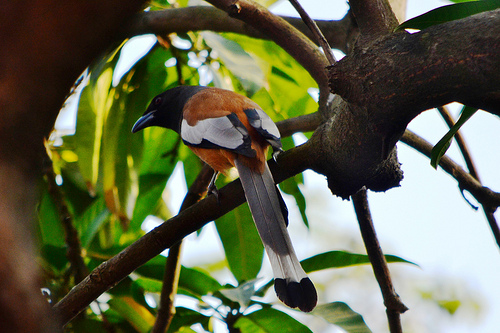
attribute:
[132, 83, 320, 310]
bird — brown, grey, black, white, alone, looking-left, cute, beautiful, colorful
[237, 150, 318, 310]
tail feathers — long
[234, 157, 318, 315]
tail — black, grey, white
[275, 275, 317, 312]
edge — black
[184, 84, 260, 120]
back — orange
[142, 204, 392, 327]
leaves — green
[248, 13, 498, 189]
branch — big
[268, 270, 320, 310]
tail — black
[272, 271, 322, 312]
tail — black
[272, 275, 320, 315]
tail — black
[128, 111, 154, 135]
beak — present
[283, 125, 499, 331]
sky — cloudy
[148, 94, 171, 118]
eye — open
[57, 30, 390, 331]
leaves — green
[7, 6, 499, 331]
tree — pictured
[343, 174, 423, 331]
branch — small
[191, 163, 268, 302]
leaf — green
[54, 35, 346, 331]
leaves — beautiful, green, group